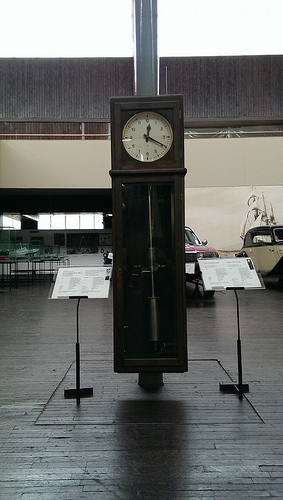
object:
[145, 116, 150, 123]
number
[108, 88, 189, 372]
clock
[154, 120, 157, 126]
number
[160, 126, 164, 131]
number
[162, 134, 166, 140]
number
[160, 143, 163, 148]
number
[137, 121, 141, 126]
number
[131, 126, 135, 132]
number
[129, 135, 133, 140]
number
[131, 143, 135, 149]
number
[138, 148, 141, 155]
number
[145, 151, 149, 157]
number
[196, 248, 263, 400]
stands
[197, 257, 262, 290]
paper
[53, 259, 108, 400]
stand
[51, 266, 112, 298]
paper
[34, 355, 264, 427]
square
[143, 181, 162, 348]
chime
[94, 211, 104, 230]
windows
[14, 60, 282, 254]
wall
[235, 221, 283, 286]
cars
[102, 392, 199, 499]
shadow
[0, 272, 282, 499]
floor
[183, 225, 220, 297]
car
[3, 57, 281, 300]
background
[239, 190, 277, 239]
ship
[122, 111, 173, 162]
12:20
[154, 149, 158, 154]
number